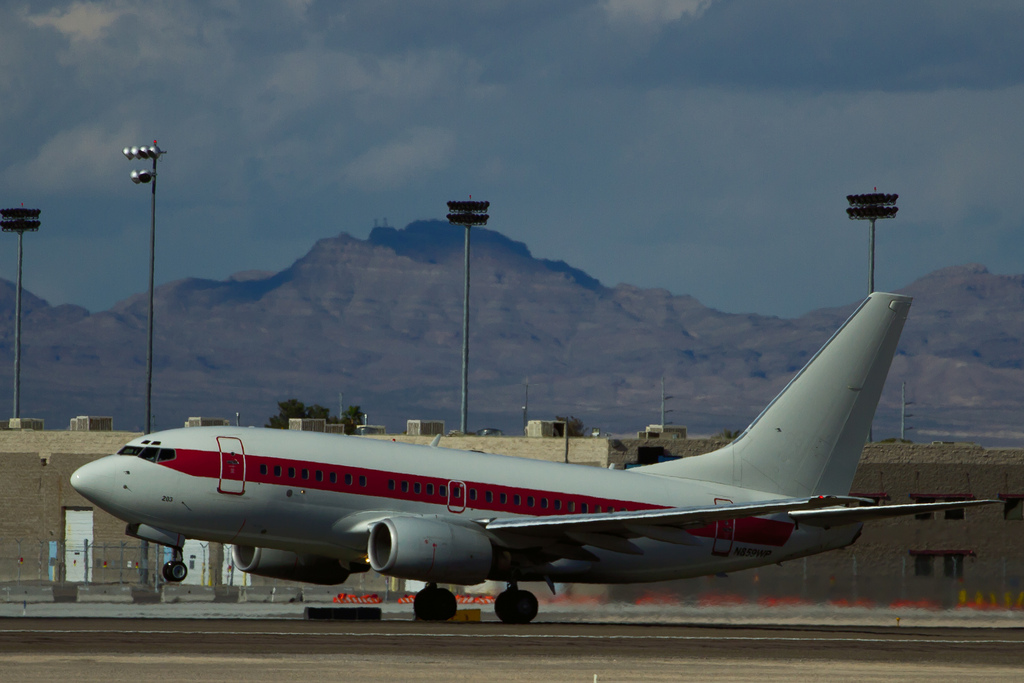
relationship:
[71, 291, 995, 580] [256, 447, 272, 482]
plane has a window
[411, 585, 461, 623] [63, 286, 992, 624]
tires of plane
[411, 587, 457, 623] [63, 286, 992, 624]
tires of plane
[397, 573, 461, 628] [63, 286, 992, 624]
tires of plane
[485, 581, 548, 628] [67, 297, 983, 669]
tires of plane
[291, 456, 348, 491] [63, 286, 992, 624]
windows on plane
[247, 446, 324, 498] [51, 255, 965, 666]
windows on plane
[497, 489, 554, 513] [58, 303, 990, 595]
windows on plane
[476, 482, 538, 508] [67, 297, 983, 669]
windows on plane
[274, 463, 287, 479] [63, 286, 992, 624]
window built into plane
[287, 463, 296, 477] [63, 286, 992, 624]
window built into plane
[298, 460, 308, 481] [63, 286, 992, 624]
window built into plane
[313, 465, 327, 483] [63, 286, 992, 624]
window built into plane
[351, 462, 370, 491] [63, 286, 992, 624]
window built into plane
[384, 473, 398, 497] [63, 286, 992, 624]
window built into plane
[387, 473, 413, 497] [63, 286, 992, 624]
window built into plane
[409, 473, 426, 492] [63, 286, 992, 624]
window built into plane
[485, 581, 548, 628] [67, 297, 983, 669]
tires of a plane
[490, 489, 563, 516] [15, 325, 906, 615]
windows on a plane